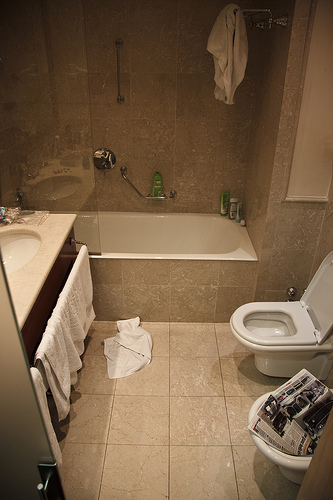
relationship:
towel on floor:
[96, 314, 161, 383] [54, 314, 316, 494]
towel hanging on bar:
[29, 243, 97, 464] [47, 232, 88, 384]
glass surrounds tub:
[1, 2, 99, 253] [18, 204, 258, 263]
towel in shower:
[205, 2, 249, 108] [3, 3, 254, 258]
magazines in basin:
[248, 366, 333, 455] [248, 389, 333, 486]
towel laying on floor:
[96, 318, 154, 383] [54, 314, 316, 494]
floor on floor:
[60, 317, 300, 498] [54, 314, 316, 494]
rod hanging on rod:
[27, 243, 96, 401] [27, 229, 87, 388]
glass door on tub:
[1, 1, 102, 255] [76, 208, 256, 319]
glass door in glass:
[1, 1, 102, 255] [1, 2, 99, 253]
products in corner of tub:
[216, 185, 247, 229] [61, 210, 257, 320]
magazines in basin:
[248, 366, 333, 455] [246, 388, 319, 484]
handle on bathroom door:
[36, 469, 55, 498] [0, 253, 67, 500]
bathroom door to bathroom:
[0, 253, 67, 500] [1, 1, 331, 496]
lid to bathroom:
[300, 251, 333, 346] [0, 0, 333, 500]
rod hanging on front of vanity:
[27, 243, 96, 401] [3, 207, 94, 445]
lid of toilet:
[300, 251, 332, 335] [229, 250, 330, 388]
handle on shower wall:
[110, 36, 125, 104] [2, 3, 267, 217]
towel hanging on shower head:
[205, 2, 249, 103] [239, 7, 275, 30]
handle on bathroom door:
[36, 462, 59, 500] [0, 253, 67, 498]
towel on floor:
[96, 318, 154, 383] [54, 314, 316, 494]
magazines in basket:
[249, 369, 328, 444] [245, 385, 312, 484]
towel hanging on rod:
[41, 314, 83, 419] [27, 243, 96, 401]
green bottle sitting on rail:
[147, 167, 166, 198] [117, 164, 176, 200]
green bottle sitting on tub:
[220, 190, 230, 217] [61, 210, 257, 320]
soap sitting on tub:
[228, 195, 238, 218] [61, 210, 257, 320]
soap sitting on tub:
[236, 203, 242, 221] [61, 210, 257, 320]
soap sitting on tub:
[239, 217, 245, 227] [61, 210, 257, 320]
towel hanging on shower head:
[205, 2, 249, 103] [242, 7, 289, 31]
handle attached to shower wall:
[112, 36, 125, 104] [2, 3, 293, 210]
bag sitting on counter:
[0, 206, 50, 226] [0, 212, 78, 331]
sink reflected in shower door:
[15, 122, 94, 211] [0, 0, 102, 254]